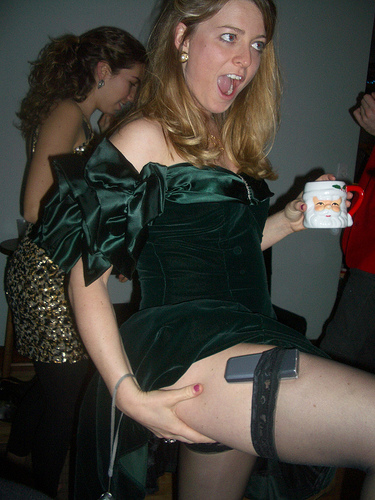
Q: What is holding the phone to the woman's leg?
A: A garter.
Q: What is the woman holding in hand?
A: A Santa Mug.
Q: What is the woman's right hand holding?
A: Her thigh.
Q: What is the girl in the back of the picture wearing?
A: Gold dress.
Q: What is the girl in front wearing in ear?
A: Earrings.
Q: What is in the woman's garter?
A: Cell phone.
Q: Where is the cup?
A: Woman's hand.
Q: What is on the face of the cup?
A: Santa Clause.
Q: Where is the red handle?
A: Cup.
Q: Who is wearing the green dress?
A: The woman.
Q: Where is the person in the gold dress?
A: Behind the woman in the green dress.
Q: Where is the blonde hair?
A: On the woman's head.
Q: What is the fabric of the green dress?
A: Velvet.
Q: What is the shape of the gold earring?
A: Circle.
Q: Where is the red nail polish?
A: Woman's fingernails.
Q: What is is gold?
A: The dress.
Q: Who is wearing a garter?
A: The girl.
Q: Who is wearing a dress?
A: The woman.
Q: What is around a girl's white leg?
A: A black garter band.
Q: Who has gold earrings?
A: A blonde girl.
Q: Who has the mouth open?
A: The blonde girl.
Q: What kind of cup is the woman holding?
A: Santa Claus cup.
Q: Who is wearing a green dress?
A: Blonde woman.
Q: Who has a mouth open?
A: Woman in green dress.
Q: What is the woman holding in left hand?
A: Santa mug.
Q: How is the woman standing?
A: With one leg up.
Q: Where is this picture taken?
A: Party.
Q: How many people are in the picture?
A: Three.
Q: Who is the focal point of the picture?
A: Woman.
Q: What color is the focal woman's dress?
A: Green.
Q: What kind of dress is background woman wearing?
A: Sequin.